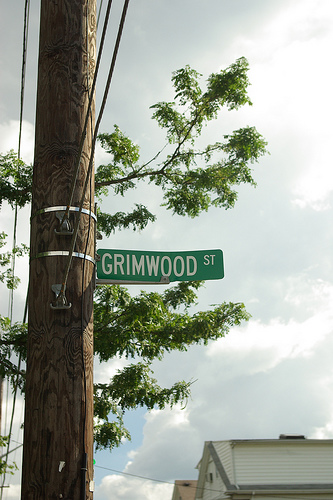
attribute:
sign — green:
[95, 246, 225, 284]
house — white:
[197, 420, 327, 495]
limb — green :
[94, 282, 240, 353]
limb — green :
[4, 319, 23, 379]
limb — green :
[93, 362, 193, 449]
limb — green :
[4, 151, 33, 208]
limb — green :
[94, 52, 268, 232]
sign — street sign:
[86, 204, 272, 313]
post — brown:
[30, 30, 100, 223]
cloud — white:
[249, 10, 332, 207]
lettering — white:
[103, 252, 197, 275]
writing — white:
[101, 253, 216, 276]